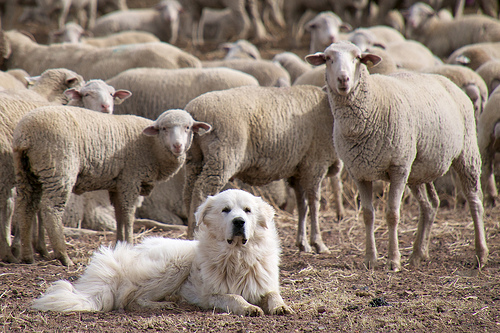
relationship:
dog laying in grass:
[43, 188, 313, 325] [285, 256, 500, 333]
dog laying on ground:
[43, 188, 313, 325] [0, 193, 482, 331]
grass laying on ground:
[285, 256, 500, 333] [0, 193, 482, 331]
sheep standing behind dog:
[299, 36, 496, 274] [34, 187, 291, 318]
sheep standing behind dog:
[180, 71, 345, 253] [34, 187, 291, 318]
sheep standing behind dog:
[9, 91, 217, 274] [34, 187, 291, 318]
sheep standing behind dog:
[98, 65, 258, 118] [34, 187, 291, 318]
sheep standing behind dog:
[205, 53, 294, 86] [34, 187, 291, 318]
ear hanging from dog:
[192, 194, 216, 230] [34, 187, 291, 318]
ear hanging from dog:
[252, 195, 276, 230] [34, 187, 291, 318]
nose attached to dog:
[226, 203, 253, 233] [34, 187, 291, 318]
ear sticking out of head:
[305, 50, 329, 67] [318, 38, 365, 98]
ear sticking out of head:
[354, 48, 382, 68] [318, 38, 365, 98]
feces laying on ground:
[369, 294, 389, 310] [0, 193, 482, 331]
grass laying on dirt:
[285, 256, 500, 333] [1, 202, 484, 328]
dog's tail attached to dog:
[28, 239, 123, 311] [34, 187, 291, 318]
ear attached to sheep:
[180, 113, 227, 144] [9, 91, 217, 274]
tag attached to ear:
[196, 126, 207, 138] [180, 113, 227, 144]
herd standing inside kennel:
[10, 22, 498, 220] [1, 2, 484, 330]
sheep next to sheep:
[9, 91, 210, 258] [1, 70, 134, 261]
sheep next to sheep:
[299, 9, 363, 64] [2, 1, 499, 275]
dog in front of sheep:
[26, 188, 313, 325] [221, 24, 498, 268]